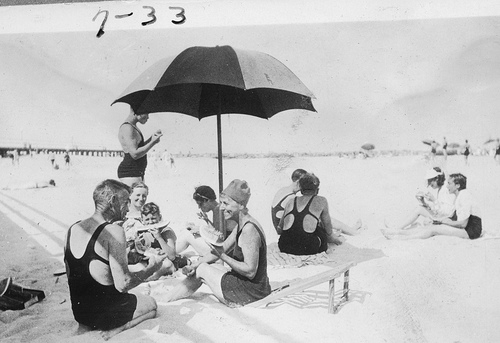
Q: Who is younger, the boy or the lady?
A: The boy is younger than the lady.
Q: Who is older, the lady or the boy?
A: The lady is older than the boy.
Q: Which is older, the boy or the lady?
A: The lady is older than the boy.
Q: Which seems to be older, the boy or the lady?
A: The lady is older than the boy.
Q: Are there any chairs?
A: Yes, there is a chair.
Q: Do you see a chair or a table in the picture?
A: Yes, there is a chair.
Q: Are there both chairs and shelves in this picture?
A: No, there is a chair but no shelves.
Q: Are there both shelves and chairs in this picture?
A: No, there is a chair but no shelves.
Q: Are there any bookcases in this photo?
A: No, there are no bookcases.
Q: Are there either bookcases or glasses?
A: No, there are no bookcases or glasses.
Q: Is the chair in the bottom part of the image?
A: Yes, the chair is in the bottom of the image.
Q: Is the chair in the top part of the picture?
A: No, the chair is in the bottom of the image.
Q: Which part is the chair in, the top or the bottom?
A: The chair is in the bottom of the image.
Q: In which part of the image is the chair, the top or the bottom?
A: The chair is in the bottom of the image.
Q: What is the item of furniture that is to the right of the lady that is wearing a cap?
A: The piece of furniture is a chair.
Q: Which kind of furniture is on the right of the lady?
A: The piece of furniture is a chair.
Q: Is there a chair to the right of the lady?
A: Yes, there is a chair to the right of the lady.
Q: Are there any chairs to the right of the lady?
A: Yes, there is a chair to the right of the lady.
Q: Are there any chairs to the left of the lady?
A: No, the chair is to the right of the lady.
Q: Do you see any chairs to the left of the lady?
A: No, the chair is to the right of the lady.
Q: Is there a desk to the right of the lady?
A: No, there is a chair to the right of the lady.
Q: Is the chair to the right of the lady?
A: Yes, the chair is to the right of the lady.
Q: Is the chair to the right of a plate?
A: No, the chair is to the right of the lady.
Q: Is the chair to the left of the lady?
A: No, the chair is to the right of the lady.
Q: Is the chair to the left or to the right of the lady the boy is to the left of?
A: The chair is to the right of the lady.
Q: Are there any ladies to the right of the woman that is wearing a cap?
A: Yes, there is a lady to the right of the woman.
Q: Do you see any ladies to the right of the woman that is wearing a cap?
A: Yes, there is a lady to the right of the woman.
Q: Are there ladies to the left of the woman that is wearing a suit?
A: No, the lady is to the right of the woman.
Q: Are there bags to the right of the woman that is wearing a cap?
A: No, there is a lady to the right of the woman.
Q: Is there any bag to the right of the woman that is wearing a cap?
A: No, there is a lady to the right of the woman.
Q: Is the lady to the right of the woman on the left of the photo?
A: Yes, the lady is to the right of the woman.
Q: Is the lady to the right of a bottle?
A: No, the lady is to the right of the woman.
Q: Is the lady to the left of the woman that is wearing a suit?
A: No, the lady is to the right of the woman.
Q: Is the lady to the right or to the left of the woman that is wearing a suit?
A: The lady is to the right of the woman.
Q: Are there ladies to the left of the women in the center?
A: Yes, there is a lady to the left of the women.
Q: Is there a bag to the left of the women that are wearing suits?
A: No, there is a lady to the left of the women.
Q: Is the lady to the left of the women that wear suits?
A: Yes, the lady is to the left of the women.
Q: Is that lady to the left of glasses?
A: No, the lady is to the left of the women.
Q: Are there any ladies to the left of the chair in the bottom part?
A: Yes, there is a lady to the left of the chair.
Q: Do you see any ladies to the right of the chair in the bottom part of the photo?
A: No, the lady is to the left of the chair.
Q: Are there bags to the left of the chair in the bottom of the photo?
A: No, there is a lady to the left of the chair.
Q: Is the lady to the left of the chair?
A: Yes, the lady is to the left of the chair.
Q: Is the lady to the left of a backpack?
A: No, the lady is to the left of the chair.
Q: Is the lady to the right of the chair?
A: No, the lady is to the left of the chair.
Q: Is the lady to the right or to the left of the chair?
A: The lady is to the left of the chair.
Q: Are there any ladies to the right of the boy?
A: Yes, there is a lady to the right of the boy.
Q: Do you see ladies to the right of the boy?
A: Yes, there is a lady to the right of the boy.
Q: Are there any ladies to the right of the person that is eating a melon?
A: Yes, there is a lady to the right of the boy.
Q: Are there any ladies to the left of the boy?
A: No, the lady is to the right of the boy.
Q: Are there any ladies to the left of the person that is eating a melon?
A: No, the lady is to the right of the boy.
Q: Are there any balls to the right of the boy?
A: No, there is a lady to the right of the boy.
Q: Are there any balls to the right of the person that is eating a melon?
A: No, there is a lady to the right of the boy.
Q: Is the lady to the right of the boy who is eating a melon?
A: Yes, the lady is to the right of the boy.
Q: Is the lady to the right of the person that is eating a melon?
A: Yes, the lady is to the right of the boy.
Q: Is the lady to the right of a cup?
A: No, the lady is to the right of the boy.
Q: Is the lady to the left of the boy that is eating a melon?
A: No, the lady is to the right of the boy.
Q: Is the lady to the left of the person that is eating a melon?
A: No, the lady is to the right of the boy.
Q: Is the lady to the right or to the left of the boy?
A: The lady is to the right of the boy.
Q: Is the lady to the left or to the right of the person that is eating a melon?
A: The lady is to the right of the boy.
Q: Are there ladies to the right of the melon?
A: Yes, there is a lady to the right of the melon.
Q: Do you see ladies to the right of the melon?
A: Yes, there is a lady to the right of the melon.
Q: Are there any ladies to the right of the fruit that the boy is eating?
A: Yes, there is a lady to the right of the melon.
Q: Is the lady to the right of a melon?
A: Yes, the lady is to the right of a melon.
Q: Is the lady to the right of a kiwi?
A: No, the lady is to the right of a melon.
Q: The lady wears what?
A: The lady wears a cap.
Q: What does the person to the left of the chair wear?
A: The lady wears a cap.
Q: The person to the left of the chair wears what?
A: The lady wears a cap.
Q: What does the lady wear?
A: The lady wears a cap.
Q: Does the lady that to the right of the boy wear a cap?
A: Yes, the lady wears a cap.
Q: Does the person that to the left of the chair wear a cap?
A: Yes, the lady wears a cap.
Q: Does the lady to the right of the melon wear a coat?
A: No, the lady wears a cap.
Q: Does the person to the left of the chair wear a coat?
A: No, the lady wears a cap.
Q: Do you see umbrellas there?
A: Yes, there is an umbrella.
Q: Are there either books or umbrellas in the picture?
A: Yes, there is an umbrella.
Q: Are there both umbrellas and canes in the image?
A: No, there is an umbrella but no canes.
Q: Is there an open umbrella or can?
A: Yes, there is an open umbrella.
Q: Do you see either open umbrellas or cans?
A: Yes, there is an open umbrella.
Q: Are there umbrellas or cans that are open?
A: Yes, the umbrella is open.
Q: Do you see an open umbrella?
A: Yes, there is an open umbrella.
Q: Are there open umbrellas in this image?
A: Yes, there is an open umbrella.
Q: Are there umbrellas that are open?
A: Yes, there is an umbrella that is open.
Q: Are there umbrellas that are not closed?
A: Yes, there is a open umbrella.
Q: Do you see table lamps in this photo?
A: No, there are no table lamps.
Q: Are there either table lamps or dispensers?
A: No, there are no table lamps or dispensers.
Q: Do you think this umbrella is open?
A: Yes, the umbrella is open.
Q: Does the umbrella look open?
A: Yes, the umbrella is open.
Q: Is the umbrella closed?
A: No, the umbrella is open.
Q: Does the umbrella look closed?
A: No, the umbrella is open.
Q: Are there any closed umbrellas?
A: No, there is an umbrella but it is open.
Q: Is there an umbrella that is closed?
A: No, there is an umbrella but it is open.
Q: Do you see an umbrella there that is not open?
A: No, there is an umbrella but it is open.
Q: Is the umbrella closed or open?
A: The umbrella is open.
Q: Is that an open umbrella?
A: Yes, that is an open umbrella.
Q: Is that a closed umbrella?
A: No, that is an open umbrella.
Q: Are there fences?
A: No, there are no fences.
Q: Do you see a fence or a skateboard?
A: No, there are no fences or skateboards.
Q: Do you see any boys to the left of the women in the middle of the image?
A: Yes, there is a boy to the left of the women.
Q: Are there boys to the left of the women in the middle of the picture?
A: Yes, there is a boy to the left of the women.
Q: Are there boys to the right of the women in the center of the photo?
A: No, the boy is to the left of the women.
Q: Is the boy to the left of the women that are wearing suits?
A: Yes, the boy is to the left of the women.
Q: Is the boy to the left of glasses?
A: No, the boy is to the left of the women.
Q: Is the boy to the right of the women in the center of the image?
A: No, the boy is to the left of the women.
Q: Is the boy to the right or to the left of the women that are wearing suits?
A: The boy is to the left of the women.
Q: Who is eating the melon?
A: The boy is eating the melon.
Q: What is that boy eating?
A: The boy is eating a melon.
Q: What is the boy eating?
A: The boy is eating a melon.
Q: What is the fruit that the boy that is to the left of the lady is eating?
A: The fruit is a melon.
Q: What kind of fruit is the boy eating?
A: The boy is eating a melon.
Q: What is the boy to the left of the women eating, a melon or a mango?
A: The boy is eating a melon.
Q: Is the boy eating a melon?
A: Yes, the boy is eating a melon.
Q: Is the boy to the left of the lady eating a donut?
A: No, the boy is eating a melon.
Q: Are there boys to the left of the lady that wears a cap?
A: Yes, there is a boy to the left of the lady.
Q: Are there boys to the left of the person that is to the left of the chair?
A: Yes, there is a boy to the left of the lady.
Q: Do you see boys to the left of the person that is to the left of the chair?
A: Yes, there is a boy to the left of the lady.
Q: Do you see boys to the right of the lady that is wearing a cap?
A: No, the boy is to the left of the lady.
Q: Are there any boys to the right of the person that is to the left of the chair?
A: No, the boy is to the left of the lady.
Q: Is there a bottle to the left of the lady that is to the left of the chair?
A: No, there is a boy to the left of the lady.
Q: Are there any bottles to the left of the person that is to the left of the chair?
A: No, there is a boy to the left of the lady.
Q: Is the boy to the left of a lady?
A: Yes, the boy is to the left of a lady.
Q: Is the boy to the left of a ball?
A: No, the boy is to the left of a lady.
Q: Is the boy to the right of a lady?
A: No, the boy is to the left of a lady.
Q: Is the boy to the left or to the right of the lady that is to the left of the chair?
A: The boy is to the left of the lady.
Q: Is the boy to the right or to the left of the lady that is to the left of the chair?
A: The boy is to the left of the lady.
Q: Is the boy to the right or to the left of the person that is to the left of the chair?
A: The boy is to the left of the lady.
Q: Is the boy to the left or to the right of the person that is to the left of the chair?
A: The boy is to the left of the lady.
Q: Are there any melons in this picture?
A: Yes, there is a melon.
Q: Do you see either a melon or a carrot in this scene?
A: Yes, there is a melon.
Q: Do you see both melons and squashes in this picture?
A: No, there is a melon but no squashes.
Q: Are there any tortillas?
A: No, there are no tortillas.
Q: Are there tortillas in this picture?
A: No, there are no tortillas.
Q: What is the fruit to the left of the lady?
A: The fruit is a melon.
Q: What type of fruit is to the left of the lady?
A: The fruit is a melon.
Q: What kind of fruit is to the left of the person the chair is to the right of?
A: The fruit is a melon.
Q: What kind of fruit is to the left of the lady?
A: The fruit is a melon.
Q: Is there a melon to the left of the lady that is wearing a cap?
A: Yes, there is a melon to the left of the lady.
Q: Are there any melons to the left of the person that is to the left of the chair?
A: Yes, there is a melon to the left of the lady.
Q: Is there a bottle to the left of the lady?
A: No, there is a melon to the left of the lady.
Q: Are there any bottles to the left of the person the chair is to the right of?
A: No, there is a melon to the left of the lady.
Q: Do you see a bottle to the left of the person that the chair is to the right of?
A: No, there is a melon to the left of the lady.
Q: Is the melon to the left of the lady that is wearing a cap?
A: Yes, the melon is to the left of the lady.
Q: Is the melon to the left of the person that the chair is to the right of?
A: Yes, the melon is to the left of the lady.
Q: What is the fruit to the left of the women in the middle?
A: The fruit is a melon.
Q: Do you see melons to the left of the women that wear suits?
A: Yes, there is a melon to the left of the women.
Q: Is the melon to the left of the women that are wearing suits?
A: Yes, the melon is to the left of the women.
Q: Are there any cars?
A: No, there are no cars.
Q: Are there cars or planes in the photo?
A: No, there are no cars or planes.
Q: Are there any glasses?
A: No, there are no glasses.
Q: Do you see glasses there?
A: No, there are no glasses.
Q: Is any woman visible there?
A: Yes, there are women.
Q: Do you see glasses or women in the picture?
A: Yes, there are women.